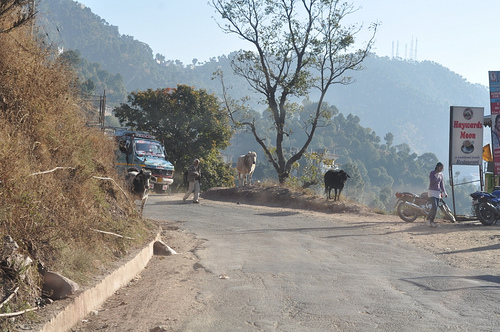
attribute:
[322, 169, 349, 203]
cow — walking, white, black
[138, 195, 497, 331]
road — paved, cracked, dusty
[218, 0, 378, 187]
tree — growing, large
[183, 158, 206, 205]
man — walking, standing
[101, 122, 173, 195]
van — blue, large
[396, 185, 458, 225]
motorcycle — blue, parked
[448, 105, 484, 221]
sign — large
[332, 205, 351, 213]
rock — large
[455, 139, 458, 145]
mark — white, spotted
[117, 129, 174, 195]
truck — blue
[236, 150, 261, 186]
calf — small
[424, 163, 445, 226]
man — walking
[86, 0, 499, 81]
sky — hazy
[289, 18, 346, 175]
twig — large